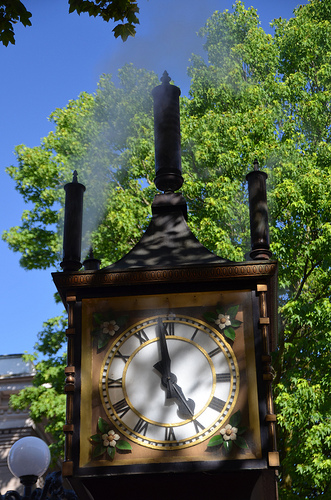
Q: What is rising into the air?
A: Steam.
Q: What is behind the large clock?
A: A large green tree.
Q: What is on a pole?
A: A large clock.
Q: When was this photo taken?
A: 4:49.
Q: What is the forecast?
A: Sunny with clear blue skies.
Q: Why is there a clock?
A: To inform people ofthe time.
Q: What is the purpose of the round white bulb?
A: To illuminate the area at night.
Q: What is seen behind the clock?
A: A large tree.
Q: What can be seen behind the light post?
A: A brick buliding.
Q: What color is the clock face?
A: White.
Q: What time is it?
A: 5:00.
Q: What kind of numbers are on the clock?
A: Roman numerals.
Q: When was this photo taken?
A: During the daytime.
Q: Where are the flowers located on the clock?
A: In the corners.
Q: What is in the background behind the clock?
A: Trees.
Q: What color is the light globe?
A: White.